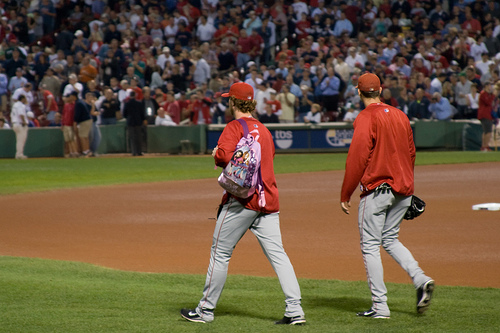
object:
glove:
[375, 182, 391, 192]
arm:
[342, 119, 370, 198]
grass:
[9, 262, 482, 331]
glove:
[403, 194, 426, 220]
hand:
[340, 194, 352, 215]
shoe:
[181, 308, 206, 323]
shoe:
[357, 308, 391, 319]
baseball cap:
[355, 73, 380, 91]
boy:
[303, 104, 321, 124]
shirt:
[306, 110, 321, 123]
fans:
[125, 31, 473, 112]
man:
[69, 91, 93, 158]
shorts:
[76, 118, 93, 137]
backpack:
[218, 129, 261, 199]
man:
[13, 94, 28, 159]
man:
[61, 94, 80, 157]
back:
[370, 103, 416, 193]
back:
[227, 117, 278, 213]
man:
[320, 70, 340, 112]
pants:
[195, 199, 305, 322]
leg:
[202, 222, 250, 298]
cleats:
[417, 281, 436, 313]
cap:
[221, 82, 255, 100]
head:
[358, 73, 382, 100]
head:
[229, 82, 255, 115]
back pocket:
[375, 187, 395, 211]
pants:
[357, 185, 432, 317]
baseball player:
[340, 72, 434, 320]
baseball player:
[179, 82, 308, 325]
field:
[4, 152, 499, 333]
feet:
[416, 280, 434, 314]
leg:
[254, 231, 302, 316]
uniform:
[339, 102, 431, 316]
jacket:
[339, 103, 416, 201]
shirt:
[320, 76, 340, 95]